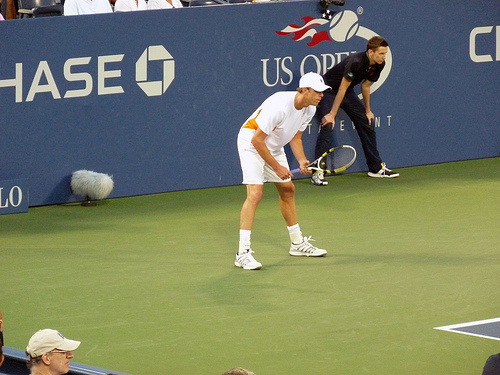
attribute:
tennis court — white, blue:
[365, 266, 489, 373]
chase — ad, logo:
[1, 43, 191, 105]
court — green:
[0, 153, 496, 369]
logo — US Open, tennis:
[256, 8, 408, 140]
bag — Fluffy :
[68, 169, 120, 206]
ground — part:
[344, 231, 481, 306]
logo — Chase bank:
[121, 29, 193, 101]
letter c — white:
[467, 25, 492, 63]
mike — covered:
[64, 164, 117, 198]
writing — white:
[4, 53, 127, 103]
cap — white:
[294, 70, 332, 95]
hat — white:
[273, 46, 343, 105]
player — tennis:
[235, 70, 327, 265]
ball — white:
[305, 11, 359, 55]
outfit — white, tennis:
[243, 88, 318, 195]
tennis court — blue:
[433, 315, 498, 355]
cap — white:
[27, 331, 80, 358]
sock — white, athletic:
[237, 228, 251, 255]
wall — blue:
[0, 0, 498, 207]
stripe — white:
[432, 313, 498, 348]